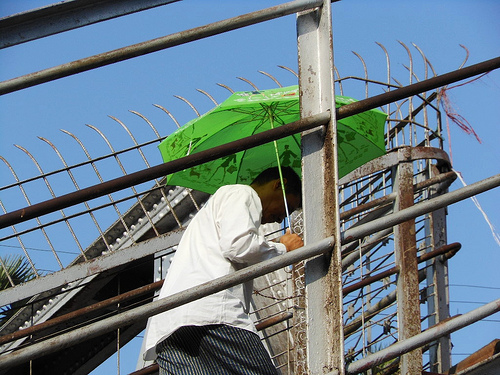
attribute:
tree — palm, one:
[340, 339, 423, 374]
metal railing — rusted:
[0, 0, 499, 374]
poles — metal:
[318, 99, 439, 296]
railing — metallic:
[2, 1, 498, 372]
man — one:
[154, 158, 311, 373]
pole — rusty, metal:
[0, 56, 498, 233]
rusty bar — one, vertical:
[0, 112, 317, 234]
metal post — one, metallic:
[392, 147, 422, 371]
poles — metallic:
[339, 146, 449, 372]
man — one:
[119, 141, 327, 364]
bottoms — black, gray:
[136, 323, 251, 373]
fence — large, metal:
[1, 35, 472, 374]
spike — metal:
[397, 33, 409, 56]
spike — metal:
[274, 60, 297, 77]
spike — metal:
[212, 81, 232, 93]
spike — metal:
[151, 97, 175, 116]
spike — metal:
[33, 133, 60, 150]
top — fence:
[1, 39, 473, 194]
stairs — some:
[366, 340, 499, 374]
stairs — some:
[0, 185, 201, 373]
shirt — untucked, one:
[131, 183, 284, 342]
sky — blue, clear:
[11, 9, 488, 362]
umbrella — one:
[153, 74, 393, 196]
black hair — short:
[251, 166, 302, 206]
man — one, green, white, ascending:
[136, 163, 302, 373]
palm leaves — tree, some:
[2, 252, 40, 284]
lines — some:
[446, 274, 488, 313]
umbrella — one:
[124, 65, 414, 203]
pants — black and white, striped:
[150, 319, 271, 372]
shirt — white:
[163, 175, 282, 335]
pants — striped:
[138, 327, 261, 373]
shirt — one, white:
[143, 181, 275, 330]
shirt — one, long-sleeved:
[138, 184, 299, 356]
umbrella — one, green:
[127, 60, 394, 274]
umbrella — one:
[161, 83, 391, 231]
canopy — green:
[119, 73, 359, 224]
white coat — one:
[142, 184, 287, 361]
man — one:
[150, 141, 310, 371]